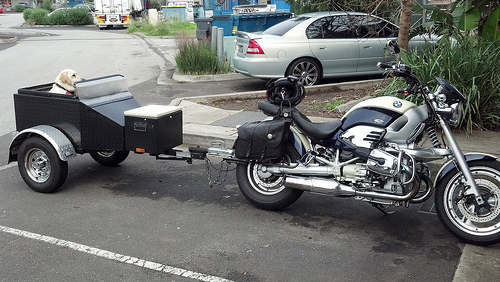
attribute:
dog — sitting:
[47, 67, 87, 95]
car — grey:
[231, 9, 461, 84]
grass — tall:
[346, 72, 436, 110]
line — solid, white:
[3, 227, 220, 279]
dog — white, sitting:
[31, 35, 136, 142]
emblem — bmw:
[285, 64, 483, 166]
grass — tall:
[379, 35, 499, 139]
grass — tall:
[387, 35, 499, 131]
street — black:
[13, 6, 457, 280]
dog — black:
[53, 70, 83, 102]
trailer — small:
[8, 67, 232, 190]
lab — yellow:
[45, 67, 80, 106]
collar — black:
[50, 80, 70, 91]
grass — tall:
[181, 40, 220, 77]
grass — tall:
[176, 37, 218, 75]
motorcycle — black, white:
[232, 60, 499, 246]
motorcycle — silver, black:
[215, 64, 496, 249]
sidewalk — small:
[93, 185, 217, 278]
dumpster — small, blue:
[211, 3, 264, 28]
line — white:
[3, 211, 310, 278]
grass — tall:
[450, 43, 475, 83]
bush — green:
[176, 32, 224, 81]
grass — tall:
[33, 7, 63, 26]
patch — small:
[101, 219, 150, 250]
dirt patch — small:
[223, 91, 249, 106]